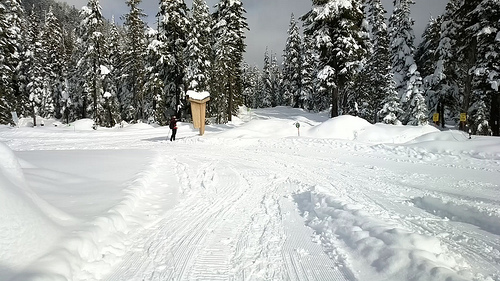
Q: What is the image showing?
A: It is showing a path.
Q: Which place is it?
A: It is a path.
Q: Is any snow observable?
A: Yes, there is snow.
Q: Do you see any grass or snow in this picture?
A: Yes, there is snow.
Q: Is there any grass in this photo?
A: No, there is no grass.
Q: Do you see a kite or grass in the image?
A: No, there are no grass or kites.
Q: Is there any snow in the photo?
A: Yes, there is snow.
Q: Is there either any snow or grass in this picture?
A: Yes, there is snow.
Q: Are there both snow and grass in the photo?
A: No, there is snow but no grass.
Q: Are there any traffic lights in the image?
A: No, there are no traffic lights.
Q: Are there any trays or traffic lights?
A: No, there are no traffic lights or trays.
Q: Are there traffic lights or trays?
A: No, there are no traffic lights or trays.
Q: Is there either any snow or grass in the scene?
A: Yes, there is snow.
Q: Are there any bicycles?
A: No, there are no bicycles.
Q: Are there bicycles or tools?
A: No, there are no bicycles or tools.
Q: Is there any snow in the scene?
A: Yes, there is snow.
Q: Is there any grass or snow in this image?
A: Yes, there is snow.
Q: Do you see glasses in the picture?
A: No, there are no glasses.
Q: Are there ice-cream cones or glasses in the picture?
A: No, there are no glasses or ice-cream cones.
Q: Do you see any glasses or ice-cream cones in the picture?
A: No, there are no glasses or ice-cream cones.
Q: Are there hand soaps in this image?
A: No, there are no hand soaps.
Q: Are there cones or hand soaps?
A: No, there are no hand soaps or cones.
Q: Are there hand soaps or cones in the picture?
A: No, there are no hand soaps or cones.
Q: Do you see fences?
A: No, there are no fences.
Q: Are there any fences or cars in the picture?
A: No, there are no fences or cars.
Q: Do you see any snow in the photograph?
A: Yes, there is snow.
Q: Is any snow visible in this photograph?
A: Yes, there is snow.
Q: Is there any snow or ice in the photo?
A: Yes, there is snow.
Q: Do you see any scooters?
A: No, there are no scooters.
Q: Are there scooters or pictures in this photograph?
A: No, there are no scooters or pictures.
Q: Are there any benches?
A: No, there are no benches.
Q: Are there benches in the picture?
A: No, there are no benches.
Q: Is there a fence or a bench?
A: No, there are no benches or fences.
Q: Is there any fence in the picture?
A: No, there are no fences.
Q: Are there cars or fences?
A: No, there are no fences or cars.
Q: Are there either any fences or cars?
A: No, there are no fences or cars.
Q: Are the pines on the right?
A: Yes, the pines are on the right of the image.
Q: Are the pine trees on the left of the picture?
A: No, the pine trees are on the right of the image.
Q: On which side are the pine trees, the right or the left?
A: The pine trees are on the right of the image.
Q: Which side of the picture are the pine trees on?
A: The pine trees are on the right of the image.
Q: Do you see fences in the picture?
A: No, there are no fences.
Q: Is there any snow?
A: Yes, there is snow.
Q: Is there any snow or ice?
A: Yes, there is snow.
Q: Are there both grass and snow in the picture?
A: No, there is snow but no grass.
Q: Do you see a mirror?
A: No, there are no mirrors.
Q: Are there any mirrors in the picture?
A: No, there are no mirrors.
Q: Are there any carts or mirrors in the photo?
A: No, there are no mirrors or carts.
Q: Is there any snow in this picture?
A: Yes, there is snow.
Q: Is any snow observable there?
A: Yes, there is snow.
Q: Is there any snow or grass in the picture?
A: Yes, there is snow.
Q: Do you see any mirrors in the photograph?
A: No, there are no mirrors.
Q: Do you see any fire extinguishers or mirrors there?
A: No, there are no mirrors or fire extinguishers.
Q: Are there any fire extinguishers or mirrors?
A: No, there are no mirrors or fire extinguishers.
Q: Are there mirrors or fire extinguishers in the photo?
A: No, there are no mirrors or fire extinguishers.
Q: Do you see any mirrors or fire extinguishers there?
A: No, there are no mirrors or fire extinguishers.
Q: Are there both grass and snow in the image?
A: No, there is snow but no grass.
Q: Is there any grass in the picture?
A: No, there is no grass.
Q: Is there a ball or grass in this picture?
A: No, there are no grass or balls.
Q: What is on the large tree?
A: The snow is on the tree.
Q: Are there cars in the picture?
A: No, there are no cars.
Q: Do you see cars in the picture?
A: No, there are no cars.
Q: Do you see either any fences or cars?
A: No, there are no cars or fences.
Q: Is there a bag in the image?
A: No, there are no bags.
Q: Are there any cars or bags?
A: No, there are no bags or cars.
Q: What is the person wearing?
A: The person is wearing a snowsuit.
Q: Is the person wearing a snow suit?
A: Yes, the person is wearing a snow suit.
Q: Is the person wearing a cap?
A: No, the person is wearing a snow suit.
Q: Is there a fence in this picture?
A: No, there are no fences.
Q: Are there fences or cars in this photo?
A: No, there are no fences or cars.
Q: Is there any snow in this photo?
A: Yes, there is snow.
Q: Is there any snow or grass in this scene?
A: Yes, there is snow.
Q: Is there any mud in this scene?
A: No, there is no mud.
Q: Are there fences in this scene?
A: No, there are no fences.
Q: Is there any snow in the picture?
A: Yes, there is snow.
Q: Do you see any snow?
A: Yes, there is snow.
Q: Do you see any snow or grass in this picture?
A: Yes, there is snow.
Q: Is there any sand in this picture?
A: No, there is no sand.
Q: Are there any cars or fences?
A: No, there are no fences or cars.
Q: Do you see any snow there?
A: Yes, there is snow.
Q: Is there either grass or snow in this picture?
A: Yes, there is snow.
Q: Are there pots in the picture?
A: No, there are no pots.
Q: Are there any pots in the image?
A: No, there are no pots.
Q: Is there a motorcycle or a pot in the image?
A: No, there are no pots or motorcycles.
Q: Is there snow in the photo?
A: Yes, there is snow.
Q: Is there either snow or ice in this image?
A: Yes, there is snow.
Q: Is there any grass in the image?
A: No, there is no grass.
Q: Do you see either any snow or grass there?
A: Yes, there is snow.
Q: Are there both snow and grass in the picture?
A: No, there is snow but no grass.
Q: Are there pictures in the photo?
A: No, there are no pictures.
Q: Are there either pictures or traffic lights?
A: No, there are no pictures or traffic lights.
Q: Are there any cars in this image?
A: No, there are no cars.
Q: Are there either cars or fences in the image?
A: No, there are no cars or fences.